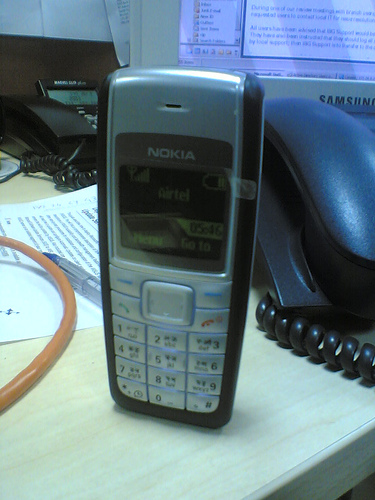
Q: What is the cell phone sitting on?
A: A desk.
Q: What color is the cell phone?
A: Black and silver.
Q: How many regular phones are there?
A: 2.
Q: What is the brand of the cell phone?
A: Nokia.